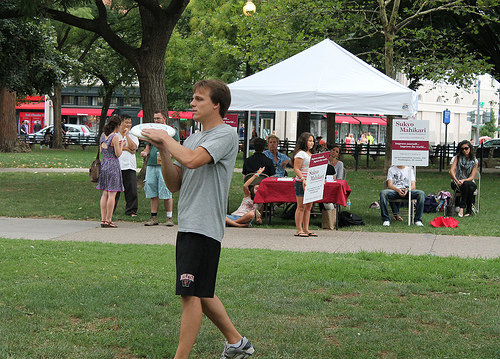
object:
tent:
[202, 37, 419, 118]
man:
[135, 77, 256, 359]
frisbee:
[130, 123, 176, 141]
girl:
[292, 132, 319, 238]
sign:
[303, 151, 331, 205]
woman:
[449, 139, 480, 218]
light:
[242, 0, 256, 17]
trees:
[0, 0, 195, 188]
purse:
[89, 141, 102, 183]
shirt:
[172, 123, 239, 244]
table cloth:
[253, 176, 352, 207]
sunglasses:
[460, 146, 471, 151]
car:
[29, 123, 98, 145]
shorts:
[174, 230, 221, 298]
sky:
[387, 68, 500, 115]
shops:
[15, 94, 50, 142]